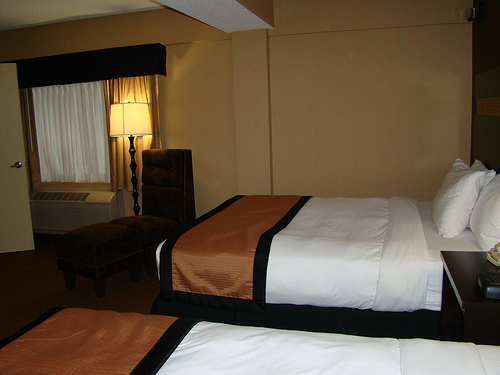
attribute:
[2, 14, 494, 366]
bedroom — neat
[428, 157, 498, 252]
white pillows — White 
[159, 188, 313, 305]
stripe — brown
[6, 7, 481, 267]
wall — tan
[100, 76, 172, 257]
lamp — tall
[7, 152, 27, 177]
handle — silver 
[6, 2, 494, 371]
room — hotel 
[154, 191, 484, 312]
bed — top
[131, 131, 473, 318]
bed — white bed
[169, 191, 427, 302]
sheets — White 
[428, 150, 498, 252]
pillows —  three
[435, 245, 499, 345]
nightstand — brown 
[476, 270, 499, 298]
alarm clock — black alarm  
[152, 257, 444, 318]
bedskirt — black 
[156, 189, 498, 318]
bed — white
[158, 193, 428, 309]
comforter — orange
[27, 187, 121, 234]
radiator — beige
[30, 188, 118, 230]
unit — heating, cooling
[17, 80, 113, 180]
curtain — white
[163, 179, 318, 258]
runner — black, gold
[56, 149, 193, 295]
lounge chair — elongated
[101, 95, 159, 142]
lampshade —  white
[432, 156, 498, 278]
pillows — white, standing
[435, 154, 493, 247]
pillowcases. — White 